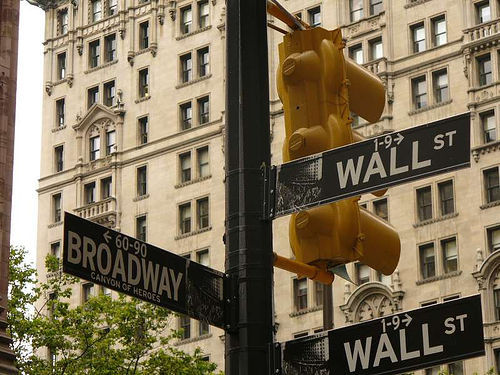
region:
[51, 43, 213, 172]
this is s building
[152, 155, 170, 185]
this is the wall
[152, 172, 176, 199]
the wall is cream in color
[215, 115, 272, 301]
this is a pole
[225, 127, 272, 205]
the pole is black in color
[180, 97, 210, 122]
these are the windows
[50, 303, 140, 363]
thee are the leaves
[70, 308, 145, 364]
the leaves are green in color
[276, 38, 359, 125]
this is a traffic light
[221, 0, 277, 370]
metal black pole supporting street signs and traffic light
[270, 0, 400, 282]
yellow traffic light on pole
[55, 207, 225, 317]
black street sign in front of tree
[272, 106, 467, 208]
black street sign above street sign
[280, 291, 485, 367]
black street sign below street sign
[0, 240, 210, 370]
green tree behind black street sign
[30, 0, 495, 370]
large white building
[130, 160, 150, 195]
glass window on building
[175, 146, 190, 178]
glass window next to window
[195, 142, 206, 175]
window next to window on building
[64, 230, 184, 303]
white lettering on a black street sign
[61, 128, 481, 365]
three street signs on a post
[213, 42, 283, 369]
a black metal post holding street signs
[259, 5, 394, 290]
a yellow stop light mounted to the post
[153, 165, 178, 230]
white stone walls of a building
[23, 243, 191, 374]
a tree growing near the post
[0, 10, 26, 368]
brown stone column of a building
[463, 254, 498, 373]
arched stone windows of the building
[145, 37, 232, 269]
many windows on the side of the building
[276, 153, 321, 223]
grey picture on the street sign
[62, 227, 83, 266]
The letter is white.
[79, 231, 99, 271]
The letter is white.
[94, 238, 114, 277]
The letter is white.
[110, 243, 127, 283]
The letter is white.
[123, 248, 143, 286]
The letter is white.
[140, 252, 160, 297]
The letter is white.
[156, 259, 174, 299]
The letter is white.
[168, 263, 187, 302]
The letter is white.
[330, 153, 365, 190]
The letter is white.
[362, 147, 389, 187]
The letter is white.